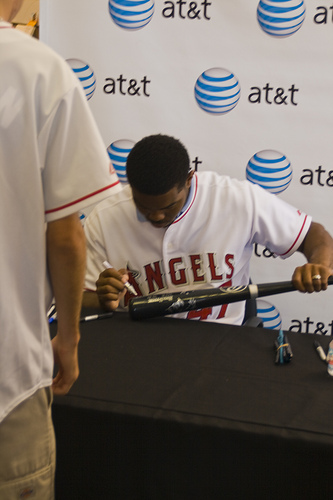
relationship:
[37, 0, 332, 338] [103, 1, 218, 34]
banner says at&t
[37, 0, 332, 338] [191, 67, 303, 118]
banner says at&t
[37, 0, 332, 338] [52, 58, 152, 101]
banner says at&t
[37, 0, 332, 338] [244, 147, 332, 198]
banner says at&t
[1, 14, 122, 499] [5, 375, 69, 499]
man wearing shorts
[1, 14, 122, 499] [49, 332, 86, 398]
man has hand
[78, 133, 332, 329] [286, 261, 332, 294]
man has hand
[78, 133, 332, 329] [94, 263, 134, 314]
man has hand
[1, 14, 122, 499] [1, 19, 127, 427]
man wearing shirt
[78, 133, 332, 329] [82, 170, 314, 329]
man wearing shirt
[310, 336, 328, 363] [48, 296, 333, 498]
pen on table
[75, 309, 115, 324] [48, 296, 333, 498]
pen on table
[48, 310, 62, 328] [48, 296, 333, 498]
pen on table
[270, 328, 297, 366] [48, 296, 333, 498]
pens are on table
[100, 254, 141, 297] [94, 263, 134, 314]
pen in hand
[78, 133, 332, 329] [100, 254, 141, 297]
man holding pen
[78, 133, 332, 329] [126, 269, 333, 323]
man holding baseball bat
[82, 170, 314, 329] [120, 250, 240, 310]
shirt says angels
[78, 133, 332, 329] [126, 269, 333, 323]
man signing baseball bat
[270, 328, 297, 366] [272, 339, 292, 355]
pens have rubber band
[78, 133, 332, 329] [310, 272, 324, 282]
man has ring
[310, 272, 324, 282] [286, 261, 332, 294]
ring on hand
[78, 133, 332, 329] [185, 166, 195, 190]
man has ear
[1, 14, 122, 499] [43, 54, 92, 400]
man had arm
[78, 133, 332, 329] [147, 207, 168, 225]
man has nose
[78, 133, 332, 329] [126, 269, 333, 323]
man looking at baseball bat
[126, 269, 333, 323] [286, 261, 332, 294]
baseball bat in hand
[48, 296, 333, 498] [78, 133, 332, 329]
table under man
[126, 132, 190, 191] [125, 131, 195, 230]
hair on head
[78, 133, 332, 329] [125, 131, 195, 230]
man has head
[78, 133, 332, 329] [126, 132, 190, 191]
man has hair